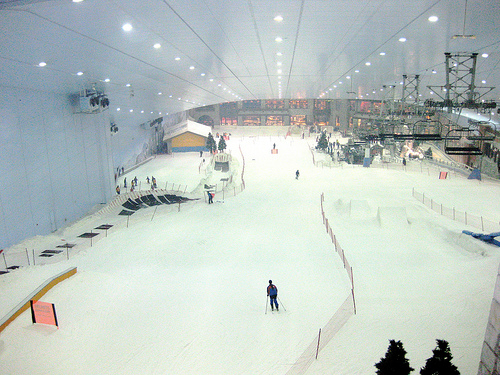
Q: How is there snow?
A: Snow machine.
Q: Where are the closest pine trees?
A: Bottom right.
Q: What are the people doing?
A: Skiing.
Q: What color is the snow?
A: White.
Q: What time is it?
A: No clock.